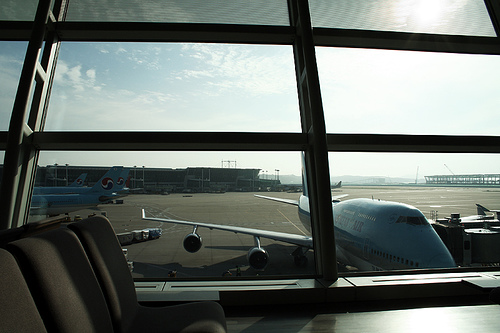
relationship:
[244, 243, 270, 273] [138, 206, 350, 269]
engines on wing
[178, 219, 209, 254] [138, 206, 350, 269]
engines on wing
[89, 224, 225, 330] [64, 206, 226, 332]
shadow on chairs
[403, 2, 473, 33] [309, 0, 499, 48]
sun on window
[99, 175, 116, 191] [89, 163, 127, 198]
circle on tail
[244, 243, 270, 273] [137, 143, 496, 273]
engines of plane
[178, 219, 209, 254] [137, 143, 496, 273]
engines of plane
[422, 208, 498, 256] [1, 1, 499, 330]
overhang of airport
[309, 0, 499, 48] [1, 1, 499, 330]
window overlooking airport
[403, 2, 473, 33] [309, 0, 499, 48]
sun through window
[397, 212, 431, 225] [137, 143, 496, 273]
windshield on plane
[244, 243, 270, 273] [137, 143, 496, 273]
engines on plane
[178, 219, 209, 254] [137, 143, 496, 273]
engines on plane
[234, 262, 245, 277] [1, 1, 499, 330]
man at airport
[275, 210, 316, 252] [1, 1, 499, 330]
line at airport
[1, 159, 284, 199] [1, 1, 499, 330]
building behind airport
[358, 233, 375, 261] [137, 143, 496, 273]
door on plane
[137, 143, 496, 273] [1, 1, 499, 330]
plane at airport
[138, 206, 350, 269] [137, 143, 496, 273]
wing of plane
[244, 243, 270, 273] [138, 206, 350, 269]
engines in wing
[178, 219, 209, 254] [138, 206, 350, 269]
engines in wing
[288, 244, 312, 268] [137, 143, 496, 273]
stabilizer of plane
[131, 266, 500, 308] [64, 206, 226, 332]
table in front of chairs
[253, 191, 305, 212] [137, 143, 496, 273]
fins of plane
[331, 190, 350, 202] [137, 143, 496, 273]
fins of plane